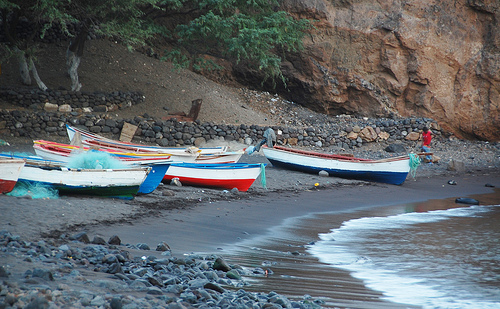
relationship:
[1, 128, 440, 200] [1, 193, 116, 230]
boats on sand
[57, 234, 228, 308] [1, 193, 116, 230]
rocks in sand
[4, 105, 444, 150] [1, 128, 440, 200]
wall behind boats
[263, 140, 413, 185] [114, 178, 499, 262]
boat on shore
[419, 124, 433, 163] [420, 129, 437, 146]
person in shirt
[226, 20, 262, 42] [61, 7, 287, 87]
leaves on tree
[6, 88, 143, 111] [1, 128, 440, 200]
rocks behind boats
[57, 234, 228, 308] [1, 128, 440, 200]
rocks in front of boats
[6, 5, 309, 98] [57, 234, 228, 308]
trees behind rocks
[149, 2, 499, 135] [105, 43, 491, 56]
rock cliff in background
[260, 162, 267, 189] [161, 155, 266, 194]
fabric from boat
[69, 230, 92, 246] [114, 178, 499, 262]
rock on shore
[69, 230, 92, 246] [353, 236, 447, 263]
rock near water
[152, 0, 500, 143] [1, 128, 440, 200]
rock cliff in middle of boats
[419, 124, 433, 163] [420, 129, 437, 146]
person wearing shirt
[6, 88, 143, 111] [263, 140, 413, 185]
rocks behind boat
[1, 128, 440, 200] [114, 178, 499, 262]
boats on shore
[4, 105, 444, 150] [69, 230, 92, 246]
wall of rock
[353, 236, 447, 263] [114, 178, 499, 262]
water on shore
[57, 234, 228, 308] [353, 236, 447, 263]
rocks near water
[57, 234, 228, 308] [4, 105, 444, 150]
rocks form wall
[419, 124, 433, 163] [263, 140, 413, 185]
person near boat